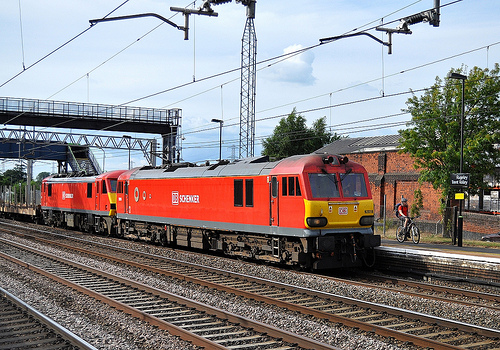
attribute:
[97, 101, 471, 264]
train station — busy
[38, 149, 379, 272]
train — short, red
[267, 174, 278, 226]
door — red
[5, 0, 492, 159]
powerlines — elevated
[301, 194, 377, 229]
front — yellow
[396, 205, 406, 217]
shirt — red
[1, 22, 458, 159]
sky — blue, clear, cloudy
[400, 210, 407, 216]
shirt — red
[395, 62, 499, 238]
tree — green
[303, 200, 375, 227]
front — yellow